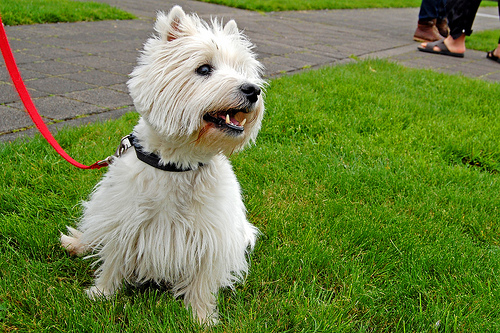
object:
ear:
[221, 18, 242, 37]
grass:
[0, 1, 134, 27]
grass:
[200, 0, 498, 9]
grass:
[464, 30, 499, 50]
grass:
[0, 58, 499, 332]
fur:
[51, 2, 273, 329]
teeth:
[237, 117, 247, 128]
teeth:
[223, 113, 231, 124]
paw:
[179, 280, 231, 330]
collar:
[126, 131, 205, 174]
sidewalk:
[3, 0, 493, 168]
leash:
[1, 22, 114, 170]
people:
[417, 1, 499, 61]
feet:
[416, 36, 466, 58]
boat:
[50, 2, 263, 322]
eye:
[193, 61, 215, 78]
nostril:
[241, 85, 259, 94]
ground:
[302, 78, 433, 331]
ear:
[157, 4, 195, 43]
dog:
[61, 3, 265, 327]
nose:
[238, 80, 263, 99]